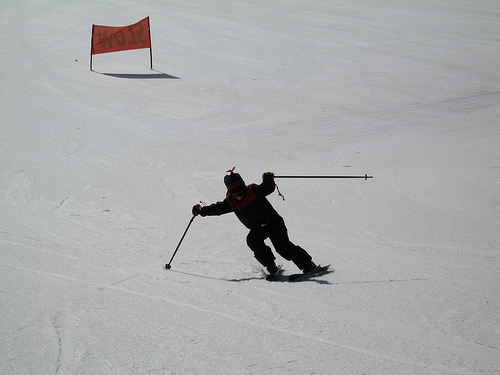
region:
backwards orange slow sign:
[77, 11, 189, 84]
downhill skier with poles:
[110, 139, 400, 308]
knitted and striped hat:
[217, 162, 251, 198]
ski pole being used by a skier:
[267, 164, 382, 196]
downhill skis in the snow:
[256, 258, 371, 280]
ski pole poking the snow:
[158, 204, 200, 293]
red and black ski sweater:
[205, 197, 320, 224]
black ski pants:
[241, 227, 320, 269]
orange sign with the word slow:
[87, 17, 182, 67]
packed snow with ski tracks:
[40, 264, 150, 336]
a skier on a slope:
[153, 142, 400, 291]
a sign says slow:
[65, 6, 185, 89]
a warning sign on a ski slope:
[60, 11, 183, 106]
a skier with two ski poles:
[120, 157, 418, 286]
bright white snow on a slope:
[18, 107, 201, 360]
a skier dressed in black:
[160, 141, 408, 297]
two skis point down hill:
[225, 237, 398, 290]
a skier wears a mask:
[191, 145, 287, 221]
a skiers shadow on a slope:
[163, 260, 439, 330]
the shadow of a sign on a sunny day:
[85, 42, 216, 119]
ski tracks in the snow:
[292, 305, 379, 370]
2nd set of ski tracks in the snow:
[404, 225, 456, 270]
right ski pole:
[154, 202, 206, 294]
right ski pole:
[271, 163, 376, 190]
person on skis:
[172, 147, 333, 288]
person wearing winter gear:
[152, 138, 337, 295]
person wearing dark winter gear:
[165, 97, 335, 304]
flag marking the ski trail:
[71, 4, 171, 70]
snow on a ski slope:
[286, 76, 433, 138]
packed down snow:
[118, 118, 223, 144]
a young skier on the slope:
[154, 145, 380, 297]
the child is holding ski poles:
[163, 162, 373, 285]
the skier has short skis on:
[258, 255, 336, 284]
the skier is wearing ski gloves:
[183, 166, 280, 216]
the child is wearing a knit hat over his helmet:
[221, 170, 248, 195]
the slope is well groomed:
[49, 112, 499, 358]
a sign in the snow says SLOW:
[78, 10, 163, 86]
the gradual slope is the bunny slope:
[6, 0, 493, 371]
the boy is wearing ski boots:
[266, 259, 321, 275]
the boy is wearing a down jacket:
[197, 182, 281, 232]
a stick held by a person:
[160, 203, 199, 269]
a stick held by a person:
[264, 167, 381, 187]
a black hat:
[218, 162, 243, 192]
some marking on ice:
[98, 280, 266, 359]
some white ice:
[379, 179, 470, 331]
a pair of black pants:
[245, 227, 312, 277]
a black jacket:
[197, 180, 277, 230]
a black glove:
[261, 170, 273, 184]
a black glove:
[190, 205, 205, 218]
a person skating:
[145, 140, 372, 323]